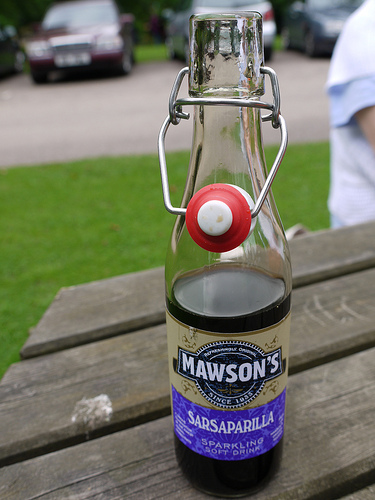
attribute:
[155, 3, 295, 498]
soft drink — sparkling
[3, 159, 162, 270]
grass — green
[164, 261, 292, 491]
liquid — purple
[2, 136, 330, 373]
grass — green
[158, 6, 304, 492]
bottle — dark, glass, clear, half-empty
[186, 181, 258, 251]
top — red, white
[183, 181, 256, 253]
stopper — red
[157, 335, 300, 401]
label — blue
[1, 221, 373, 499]
table — wooden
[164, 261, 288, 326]
liquid — black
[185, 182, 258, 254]
cover — red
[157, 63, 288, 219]
mouth holder — silver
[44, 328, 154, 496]
slats — wooden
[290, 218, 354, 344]
table — brown, wooden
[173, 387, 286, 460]
label — purple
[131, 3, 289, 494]
bottle — glass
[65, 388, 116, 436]
stain — white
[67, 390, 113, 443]
bird dropping — white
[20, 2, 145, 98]
car — Maroon 